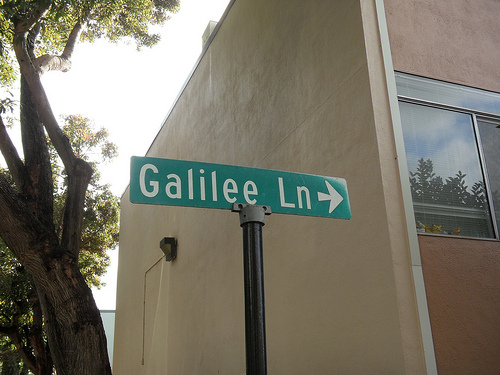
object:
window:
[393, 70, 500, 241]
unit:
[202, 20, 218, 52]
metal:
[231, 203, 271, 227]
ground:
[113, 0, 429, 375]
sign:
[129, 156, 352, 220]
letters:
[139, 164, 344, 214]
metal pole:
[239, 206, 268, 375]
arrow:
[318, 180, 344, 214]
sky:
[0, 0, 227, 311]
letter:
[200, 169, 206, 201]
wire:
[148, 236, 177, 374]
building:
[111, 0, 500, 375]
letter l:
[278, 177, 296, 208]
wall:
[116, 0, 434, 373]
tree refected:
[407, 156, 490, 239]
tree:
[0, 0, 181, 375]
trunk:
[0, 51, 110, 375]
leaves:
[95, 0, 180, 51]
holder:
[160, 237, 176, 262]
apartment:
[114, 0, 500, 375]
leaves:
[0, 115, 122, 375]